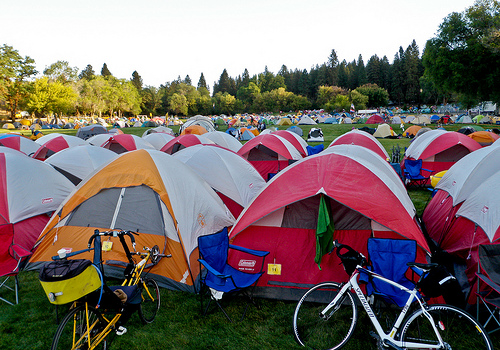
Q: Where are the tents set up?
A: On a large open field.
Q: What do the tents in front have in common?
A: Size and design.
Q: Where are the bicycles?
A: In front of the nearest tents.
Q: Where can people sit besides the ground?
A: In the blue folding chairs.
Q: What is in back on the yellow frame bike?
A: Yellow and black storage unit.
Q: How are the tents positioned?
A: In close proximity to each other?.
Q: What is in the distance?
A: Rows of trees?.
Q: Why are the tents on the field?
A: For a specific event.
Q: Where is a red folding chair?
A: The far left front.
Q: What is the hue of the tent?
A: Yellow and white.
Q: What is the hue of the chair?
A: A royal blue.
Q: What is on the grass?
A: A group of tents.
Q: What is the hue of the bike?
A: White.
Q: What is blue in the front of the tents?
A: Folding chairs.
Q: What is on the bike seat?
A: A black bag.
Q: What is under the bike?
A: Green grass.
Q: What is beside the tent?
A: A folding chair.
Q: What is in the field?
A: Tents.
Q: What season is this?
A: Summer.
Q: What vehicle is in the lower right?
A: Bicycle.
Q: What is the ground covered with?
A: Grass.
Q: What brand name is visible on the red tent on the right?
A: Coleman.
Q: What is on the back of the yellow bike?
A: Storage bag.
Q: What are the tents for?
A: Camping.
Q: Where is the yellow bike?
A: On the bottom left.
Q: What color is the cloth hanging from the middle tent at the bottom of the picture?
A: Green.